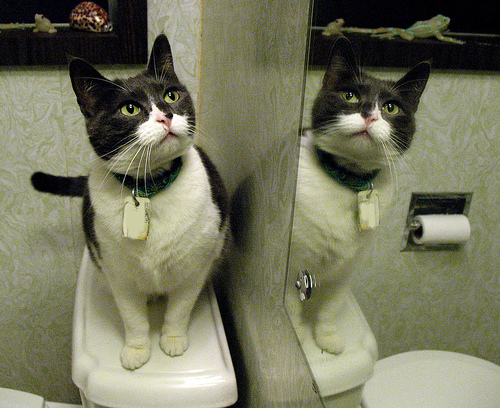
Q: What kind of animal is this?
A: Cat.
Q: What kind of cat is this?
A: Black and white short haired cat.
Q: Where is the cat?
A: Bathroom.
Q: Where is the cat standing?
A: Toilet tank.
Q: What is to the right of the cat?
A: Mirror on the wall.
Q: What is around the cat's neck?
A: Collar.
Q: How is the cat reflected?
A: Mirror.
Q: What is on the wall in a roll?
A: Toilet paper.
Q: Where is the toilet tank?
A: Under cat.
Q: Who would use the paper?
A: Person using the toilet.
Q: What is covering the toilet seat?
A: Lid.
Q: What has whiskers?
A: Cat.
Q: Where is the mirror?
A: Wall.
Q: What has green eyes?
A: Cat.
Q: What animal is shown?
A: A cat.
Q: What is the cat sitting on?
A: Back of toilet.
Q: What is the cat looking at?
A: The mirror.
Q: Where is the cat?
A: Top of toilet.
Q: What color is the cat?
A: Black and white.